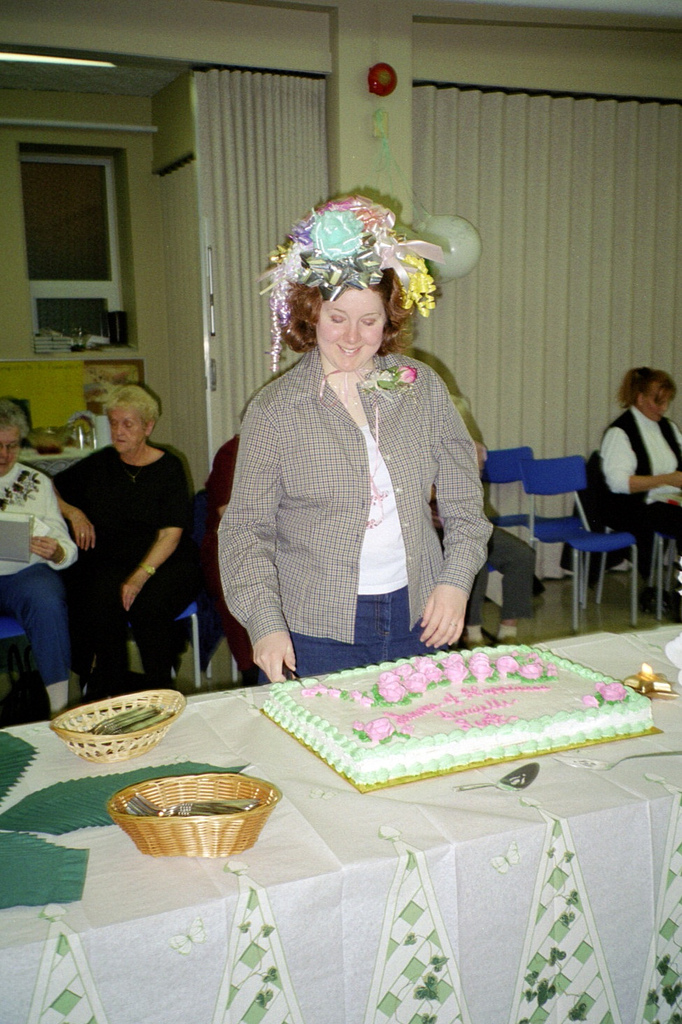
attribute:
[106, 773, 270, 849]
basket — brown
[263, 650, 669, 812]
cake — large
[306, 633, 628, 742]
pinkflowers — icing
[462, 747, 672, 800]
spatulas — silver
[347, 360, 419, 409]
flower — pink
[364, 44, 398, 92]
firealarm — red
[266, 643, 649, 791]
cake — large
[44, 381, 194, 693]
woman — older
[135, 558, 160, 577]
watch — gold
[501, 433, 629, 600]
chair — blue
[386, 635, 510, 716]
flowers — pink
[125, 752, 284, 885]
basket — wicker